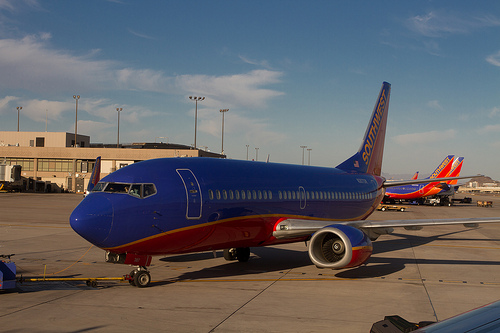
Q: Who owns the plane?
A: Southwest airlines.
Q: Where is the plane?
A: On tarmac.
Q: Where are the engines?
A: On wings.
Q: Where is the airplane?
A: Airport.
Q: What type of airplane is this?
A: Passenger.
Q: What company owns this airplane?
A: Southwest.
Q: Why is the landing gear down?
A: The airplane is on the ground.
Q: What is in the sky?
A: Clouds.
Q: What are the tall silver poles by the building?
A: Lights.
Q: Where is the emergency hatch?
A: The side of the plane around the middle.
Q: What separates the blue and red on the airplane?
A: A yellow stripe.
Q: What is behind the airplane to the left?
A: A building.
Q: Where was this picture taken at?
A: An airport.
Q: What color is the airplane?
A: Blue, red and yellow.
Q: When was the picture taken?
A: Daytime.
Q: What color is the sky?
A: Blue.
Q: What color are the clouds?
A: White.